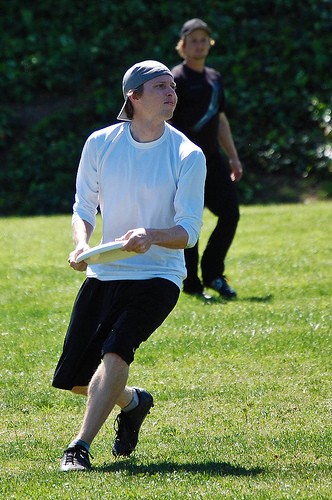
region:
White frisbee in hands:
[72, 216, 147, 276]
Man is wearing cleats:
[51, 378, 164, 483]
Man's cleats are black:
[49, 364, 161, 482]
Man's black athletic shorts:
[49, 261, 182, 390]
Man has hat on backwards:
[108, 60, 203, 148]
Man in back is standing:
[169, 3, 231, 132]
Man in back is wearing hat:
[175, 12, 218, 76]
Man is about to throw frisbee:
[61, 58, 201, 282]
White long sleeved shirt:
[67, 111, 207, 284]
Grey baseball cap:
[110, 45, 174, 125]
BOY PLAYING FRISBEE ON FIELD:
[90, 70, 252, 486]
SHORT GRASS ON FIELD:
[182, 405, 260, 478]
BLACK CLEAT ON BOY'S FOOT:
[115, 384, 160, 469]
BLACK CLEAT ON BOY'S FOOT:
[58, 428, 106, 481]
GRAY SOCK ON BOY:
[118, 388, 154, 425]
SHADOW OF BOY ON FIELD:
[129, 441, 263, 496]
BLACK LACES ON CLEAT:
[63, 439, 96, 470]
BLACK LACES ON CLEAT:
[109, 403, 124, 441]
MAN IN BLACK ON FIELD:
[184, 17, 303, 271]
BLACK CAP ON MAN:
[172, 10, 212, 39]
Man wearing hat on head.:
[122, 55, 166, 91]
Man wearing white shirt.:
[90, 152, 162, 194]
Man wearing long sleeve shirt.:
[69, 193, 199, 253]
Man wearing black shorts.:
[62, 300, 153, 348]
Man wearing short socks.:
[69, 428, 101, 449]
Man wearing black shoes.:
[51, 434, 102, 483]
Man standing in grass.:
[69, 415, 155, 466]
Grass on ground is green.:
[198, 377, 278, 448]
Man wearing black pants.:
[212, 198, 239, 246]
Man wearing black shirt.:
[182, 83, 216, 127]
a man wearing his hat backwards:
[89, 44, 177, 133]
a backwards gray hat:
[91, 39, 192, 161]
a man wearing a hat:
[168, 12, 222, 74]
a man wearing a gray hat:
[101, 46, 184, 125]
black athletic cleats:
[27, 388, 183, 498]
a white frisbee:
[59, 228, 188, 289]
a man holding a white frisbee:
[69, 66, 213, 266]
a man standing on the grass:
[158, 6, 259, 484]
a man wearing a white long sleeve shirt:
[59, 61, 206, 284]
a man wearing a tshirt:
[153, 18, 217, 172]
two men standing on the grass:
[26, 6, 303, 478]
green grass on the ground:
[0, 199, 331, 497]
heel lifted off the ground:
[107, 384, 162, 458]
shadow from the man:
[85, 455, 261, 477]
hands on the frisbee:
[54, 226, 173, 276]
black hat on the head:
[174, 13, 221, 48]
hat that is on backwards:
[103, 54, 177, 134]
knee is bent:
[201, 181, 258, 244]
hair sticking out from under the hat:
[171, 35, 224, 59]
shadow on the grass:
[207, 289, 282, 306]